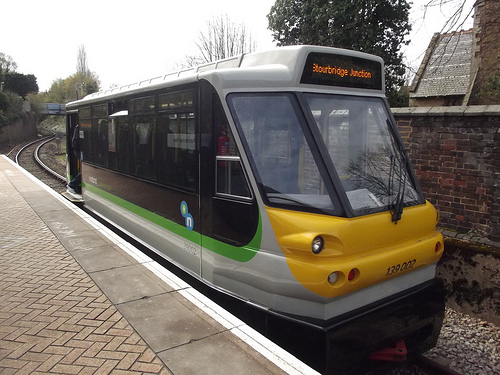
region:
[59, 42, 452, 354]
commuter rail train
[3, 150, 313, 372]
brick sidewalk in the city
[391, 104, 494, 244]
brick wall on train line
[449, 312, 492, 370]
pebbles around train track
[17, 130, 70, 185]
train track on commuter linr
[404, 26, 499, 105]
roof of building in city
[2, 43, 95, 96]
fall trees in the background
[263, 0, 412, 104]
tree with green leaves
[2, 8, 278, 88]
city sky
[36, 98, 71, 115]
bridge in background over train rail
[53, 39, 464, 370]
short train on train tracks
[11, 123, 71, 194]
curved metal train tracks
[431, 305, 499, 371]
gravel on ground on side of train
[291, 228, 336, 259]
headlight on front of train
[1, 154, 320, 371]
elevated train platform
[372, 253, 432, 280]
number on front of train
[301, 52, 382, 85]
name of destination on front of train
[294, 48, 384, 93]
digital window on front of train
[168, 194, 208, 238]
two letters in blue bubbles on side of train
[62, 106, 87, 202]
person boarding train through rear train door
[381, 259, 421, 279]
Number on front of train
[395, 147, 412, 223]
Long black windshield wiper on glass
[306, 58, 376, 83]
Location name on led sign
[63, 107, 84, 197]
Door on side of train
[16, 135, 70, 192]
Long metal railroad track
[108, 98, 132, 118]
Window open on side of bus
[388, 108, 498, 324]
Tall concrete and brick wall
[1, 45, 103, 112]
Group of trees in distance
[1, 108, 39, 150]
Long grey concrete wall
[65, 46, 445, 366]
Short passenger train engine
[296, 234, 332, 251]
the head light on the train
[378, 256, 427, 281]
black numbers on the front of the train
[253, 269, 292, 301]
the white side of the train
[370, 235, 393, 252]
the yellow front of the train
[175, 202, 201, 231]
the blue sign on the train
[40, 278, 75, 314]
the tile on the street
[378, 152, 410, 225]
the windshield wipers on the train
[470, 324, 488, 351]
the rocks on the ground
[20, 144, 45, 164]
the train tracks in the background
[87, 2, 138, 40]
the blue sky in the distance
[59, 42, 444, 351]
a small yellow, green, white, and black train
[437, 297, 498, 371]
gravel along the tracks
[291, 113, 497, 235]
a red brick wall beside a train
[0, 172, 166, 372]
a red brick paved platform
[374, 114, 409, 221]
a windshield wipe on a train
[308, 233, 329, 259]
a headlight on a train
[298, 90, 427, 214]
the large front window of a train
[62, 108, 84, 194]
a person getting onto a train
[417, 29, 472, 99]
the roof of a house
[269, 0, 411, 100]
a green leafy tree next to a house